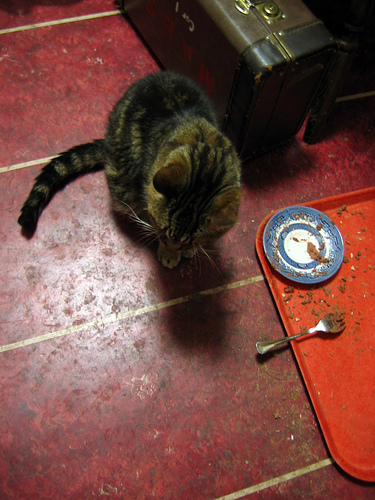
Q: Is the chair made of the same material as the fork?
A: No, the chair is made of wood and the fork is made of metal.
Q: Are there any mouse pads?
A: No, there are no mouse pads.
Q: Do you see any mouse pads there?
A: No, there are no mouse pads.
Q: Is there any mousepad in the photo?
A: No, there are no mouse pads.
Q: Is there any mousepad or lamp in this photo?
A: No, there are no mouse pads or lamps.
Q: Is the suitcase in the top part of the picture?
A: Yes, the suitcase is in the top of the image.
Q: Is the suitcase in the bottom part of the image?
A: No, the suitcase is in the top of the image.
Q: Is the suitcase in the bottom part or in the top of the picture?
A: The suitcase is in the top of the image.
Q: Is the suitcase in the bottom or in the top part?
A: The suitcase is in the top of the image.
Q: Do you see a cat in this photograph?
A: Yes, there is a cat.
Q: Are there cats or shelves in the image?
A: Yes, there is a cat.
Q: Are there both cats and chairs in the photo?
A: Yes, there are both a cat and a chair.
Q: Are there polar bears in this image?
A: No, there are no polar bears.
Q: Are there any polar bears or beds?
A: No, there are no polar bears or beds.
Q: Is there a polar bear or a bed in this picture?
A: No, there are no polar bears or beds.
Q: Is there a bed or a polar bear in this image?
A: No, there are no polar bears or beds.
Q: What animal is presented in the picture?
A: The animal is a cat.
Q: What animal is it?
A: The animal is a cat.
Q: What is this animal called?
A: This is a cat.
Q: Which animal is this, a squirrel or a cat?
A: This is a cat.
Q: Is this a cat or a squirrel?
A: This is a cat.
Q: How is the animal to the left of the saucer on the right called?
A: The animal is a cat.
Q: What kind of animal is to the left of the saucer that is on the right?
A: The animal is a cat.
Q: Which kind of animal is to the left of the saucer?
A: The animal is a cat.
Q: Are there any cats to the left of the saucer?
A: Yes, there is a cat to the left of the saucer.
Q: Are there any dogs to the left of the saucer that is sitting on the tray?
A: No, there is a cat to the left of the saucer.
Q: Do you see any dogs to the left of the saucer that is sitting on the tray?
A: No, there is a cat to the left of the saucer.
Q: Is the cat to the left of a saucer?
A: Yes, the cat is to the left of a saucer.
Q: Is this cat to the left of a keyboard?
A: No, the cat is to the left of a saucer.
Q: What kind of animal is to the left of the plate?
A: The animal is a cat.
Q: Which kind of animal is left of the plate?
A: The animal is a cat.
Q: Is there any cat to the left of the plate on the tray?
A: Yes, there is a cat to the left of the plate.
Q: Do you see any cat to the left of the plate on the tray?
A: Yes, there is a cat to the left of the plate.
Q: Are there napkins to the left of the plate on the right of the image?
A: No, there is a cat to the left of the plate.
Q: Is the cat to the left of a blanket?
A: No, the cat is to the left of a plate.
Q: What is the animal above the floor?
A: The animal is a cat.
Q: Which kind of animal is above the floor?
A: The animal is a cat.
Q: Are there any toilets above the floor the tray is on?
A: No, there is a cat above the floor.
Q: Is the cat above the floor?
A: Yes, the cat is above the floor.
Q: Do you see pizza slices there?
A: No, there are no pizza slices.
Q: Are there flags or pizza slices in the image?
A: No, there are no pizza slices or flags.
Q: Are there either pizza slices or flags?
A: No, there are no pizza slices or flags.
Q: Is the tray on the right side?
A: Yes, the tray is on the right of the image.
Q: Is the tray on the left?
A: No, the tray is on the right of the image.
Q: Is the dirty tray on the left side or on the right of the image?
A: The tray is on the right of the image.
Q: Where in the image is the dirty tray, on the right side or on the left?
A: The tray is on the right of the image.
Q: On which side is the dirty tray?
A: The tray is on the right of the image.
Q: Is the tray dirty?
A: Yes, the tray is dirty.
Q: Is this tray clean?
A: No, the tray is dirty.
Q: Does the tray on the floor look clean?
A: No, the tray is dirty.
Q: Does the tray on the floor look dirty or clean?
A: The tray is dirty.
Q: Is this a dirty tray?
A: Yes, this is a dirty tray.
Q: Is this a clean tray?
A: No, this is a dirty tray.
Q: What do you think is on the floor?
A: The tray is on the floor.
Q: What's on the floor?
A: The tray is on the floor.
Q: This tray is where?
A: The tray is on the floor.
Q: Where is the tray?
A: The tray is on the floor.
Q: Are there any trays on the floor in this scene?
A: Yes, there is a tray on the floor.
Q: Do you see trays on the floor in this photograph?
A: Yes, there is a tray on the floor.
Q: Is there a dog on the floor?
A: No, there is a tray on the floor.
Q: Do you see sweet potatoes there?
A: No, there are no sweet potatoes.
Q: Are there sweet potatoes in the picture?
A: No, there are no sweet potatoes.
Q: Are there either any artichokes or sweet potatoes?
A: No, there are no sweet potatoes or artichokes.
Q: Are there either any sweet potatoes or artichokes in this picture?
A: No, there are no sweet potatoes or artichokes.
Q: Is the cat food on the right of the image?
A: Yes, the cat food is on the right of the image.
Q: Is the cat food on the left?
A: No, the cat food is on the right of the image.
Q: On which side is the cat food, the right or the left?
A: The cat food is on the right of the image.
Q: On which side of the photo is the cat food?
A: The cat food is on the right of the image.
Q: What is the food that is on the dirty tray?
A: The food is cat food.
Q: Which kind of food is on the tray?
A: The food is cat food.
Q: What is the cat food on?
A: The cat food is on the tray.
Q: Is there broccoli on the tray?
A: No, there is cat food on the tray.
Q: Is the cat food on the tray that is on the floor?
A: Yes, the cat food is on the tray.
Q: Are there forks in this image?
A: Yes, there is a fork.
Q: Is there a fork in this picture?
A: Yes, there is a fork.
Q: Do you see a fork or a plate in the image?
A: Yes, there is a fork.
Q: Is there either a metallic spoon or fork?
A: Yes, there is a metal fork.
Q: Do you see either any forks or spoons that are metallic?
A: Yes, the fork is metallic.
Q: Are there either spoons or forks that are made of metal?
A: Yes, the fork is made of metal.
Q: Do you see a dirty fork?
A: Yes, there is a dirty fork.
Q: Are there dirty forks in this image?
A: Yes, there is a dirty fork.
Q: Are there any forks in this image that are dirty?
A: Yes, there is a fork that is dirty.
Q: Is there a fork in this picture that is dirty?
A: Yes, there is a fork that is dirty.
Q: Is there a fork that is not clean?
A: Yes, there is a dirty fork.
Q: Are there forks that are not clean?
A: Yes, there is a dirty fork.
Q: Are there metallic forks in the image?
A: Yes, there is a metal fork.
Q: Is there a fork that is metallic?
A: Yes, there is a fork that is metallic.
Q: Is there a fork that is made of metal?
A: Yes, there is a fork that is made of metal.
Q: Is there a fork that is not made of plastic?
A: Yes, there is a fork that is made of metal.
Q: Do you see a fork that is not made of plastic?
A: Yes, there is a fork that is made of metal.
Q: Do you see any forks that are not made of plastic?
A: Yes, there is a fork that is made of metal.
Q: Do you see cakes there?
A: No, there are no cakes.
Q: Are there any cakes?
A: No, there are no cakes.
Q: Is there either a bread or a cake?
A: No, there are no cakes or breads.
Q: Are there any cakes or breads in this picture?
A: No, there are no cakes or breads.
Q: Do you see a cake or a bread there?
A: No, there are no cakes or breads.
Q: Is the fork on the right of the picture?
A: Yes, the fork is on the right of the image.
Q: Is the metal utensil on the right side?
A: Yes, the fork is on the right of the image.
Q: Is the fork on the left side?
A: No, the fork is on the right of the image.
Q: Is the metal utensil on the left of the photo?
A: No, the fork is on the right of the image.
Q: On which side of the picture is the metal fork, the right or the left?
A: The fork is on the right of the image.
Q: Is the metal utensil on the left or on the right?
A: The fork is on the right of the image.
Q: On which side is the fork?
A: The fork is on the right of the image.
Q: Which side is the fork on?
A: The fork is on the right of the image.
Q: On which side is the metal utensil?
A: The fork is on the right of the image.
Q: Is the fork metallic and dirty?
A: Yes, the fork is metallic and dirty.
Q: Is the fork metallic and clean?
A: No, the fork is metallic but dirty.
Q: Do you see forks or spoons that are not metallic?
A: No, there is a fork but it is metallic.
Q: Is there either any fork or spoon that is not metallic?
A: No, there is a fork but it is metallic.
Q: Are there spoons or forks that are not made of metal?
A: No, there is a fork but it is made of metal.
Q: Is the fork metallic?
A: Yes, the fork is metallic.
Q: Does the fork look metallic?
A: Yes, the fork is metallic.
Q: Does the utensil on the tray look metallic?
A: Yes, the fork is metallic.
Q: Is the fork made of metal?
A: Yes, the fork is made of metal.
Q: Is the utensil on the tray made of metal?
A: Yes, the fork is made of metal.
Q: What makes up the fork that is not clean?
A: The fork is made of metal.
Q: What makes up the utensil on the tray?
A: The fork is made of metal.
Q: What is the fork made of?
A: The fork is made of metal.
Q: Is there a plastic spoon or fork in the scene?
A: No, there is a fork but it is metallic.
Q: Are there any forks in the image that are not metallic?
A: No, there is a fork but it is metallic.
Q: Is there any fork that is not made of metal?
A: No, there is a fork but it is made of metal.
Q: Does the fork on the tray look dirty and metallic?
A: Yes, the fork is dirty and metallic.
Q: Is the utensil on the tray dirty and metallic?
A: Yes, the fork is dirty and metallic.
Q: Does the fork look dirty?
A: Yes, the fork is dirty.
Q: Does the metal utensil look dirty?
A: Yes, the fork is dirty.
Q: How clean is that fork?
A: The fork is dirty.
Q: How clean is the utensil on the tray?
A: The fork is dirty.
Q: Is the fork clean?
A: No, the fork is dirty.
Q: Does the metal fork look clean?
A: No, the fork is dirty.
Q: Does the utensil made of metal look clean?
A: No, the fork is dirty.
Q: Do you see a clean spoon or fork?
A: No, there is a fork but it is dirty.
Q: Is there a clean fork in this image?
A: No, there is a fork but it is dirty.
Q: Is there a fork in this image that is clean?
A: No, there is a fork but it is dirty.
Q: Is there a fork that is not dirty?
A: No, there is a fork but it is dirty.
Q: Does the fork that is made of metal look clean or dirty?
A: The fork is dirty.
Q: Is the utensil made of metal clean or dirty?
A: The fork is dirty.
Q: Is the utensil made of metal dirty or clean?
A: The fork is dirty.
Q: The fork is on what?
A: The fork is on the tray.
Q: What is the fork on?
A: The fork is on the tray.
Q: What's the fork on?
A: The fork is on the tray.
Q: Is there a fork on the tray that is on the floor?
A: Yes, there is a fork on the tray.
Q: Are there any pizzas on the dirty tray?
A: No, there is a fork on the tray.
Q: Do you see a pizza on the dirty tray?
A: No, there is a fork on the tray.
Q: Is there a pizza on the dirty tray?
A: No, there is a fork on the tray.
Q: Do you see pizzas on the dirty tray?
A: No, there is a fork on the tray.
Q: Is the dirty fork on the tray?
A: Yes, the fork is on the tray.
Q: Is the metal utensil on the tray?
A: Yes, the fork is on the tray.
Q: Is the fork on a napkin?
A: No, the fork is on the tray.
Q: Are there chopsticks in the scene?
A: No, there are no chopsticks.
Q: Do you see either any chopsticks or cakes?
A: No, there are no chopsticks or cakes.